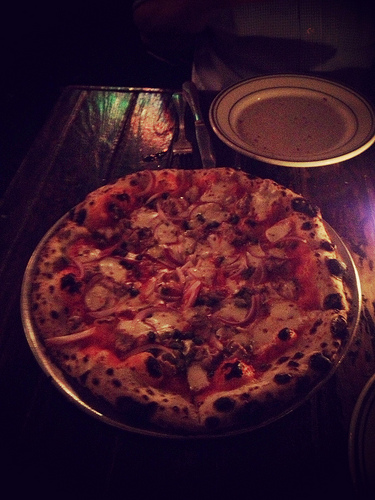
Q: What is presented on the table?
A: Pizza.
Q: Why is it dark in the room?
A: Lack of lighting.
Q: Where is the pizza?
A: On a table.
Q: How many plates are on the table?
A: Two.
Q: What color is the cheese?
A: White.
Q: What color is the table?
A: Brown.